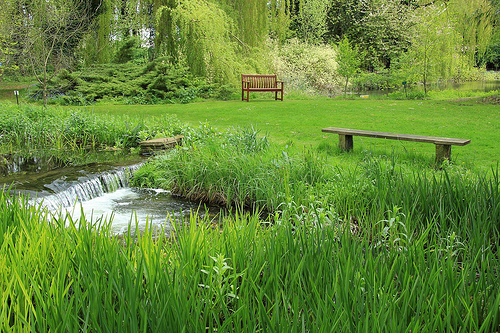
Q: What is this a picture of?
A: A lush park.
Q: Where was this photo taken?
A: In a public green space.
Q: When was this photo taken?
A: During the spring or summer.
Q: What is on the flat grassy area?
A: Two park benches.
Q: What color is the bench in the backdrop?
A: Brown-orangish.